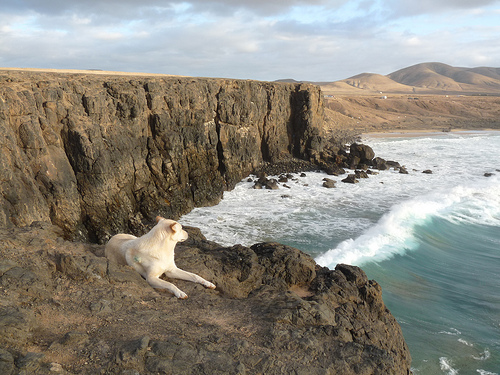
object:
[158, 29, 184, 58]
clouds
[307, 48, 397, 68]
clouds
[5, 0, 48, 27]
sky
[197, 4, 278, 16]
clouds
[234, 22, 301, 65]
clouds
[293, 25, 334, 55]
clouds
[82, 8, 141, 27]
clouds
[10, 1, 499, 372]
scene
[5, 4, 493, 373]
photo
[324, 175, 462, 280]
wave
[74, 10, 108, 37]
clouds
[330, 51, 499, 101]
hills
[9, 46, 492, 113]
background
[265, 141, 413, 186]
rocks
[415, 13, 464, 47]
clouds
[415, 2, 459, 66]
sky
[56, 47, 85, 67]
sky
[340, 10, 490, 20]
clouds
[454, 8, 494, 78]
sky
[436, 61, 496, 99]
dunes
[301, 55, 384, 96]
dunes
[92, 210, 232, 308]
dog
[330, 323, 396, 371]
rocks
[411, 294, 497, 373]
ocean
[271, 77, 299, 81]
hills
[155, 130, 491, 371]
water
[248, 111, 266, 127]
rocks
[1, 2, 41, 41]
clouds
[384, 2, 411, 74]
sky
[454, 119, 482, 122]
land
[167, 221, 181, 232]
ears